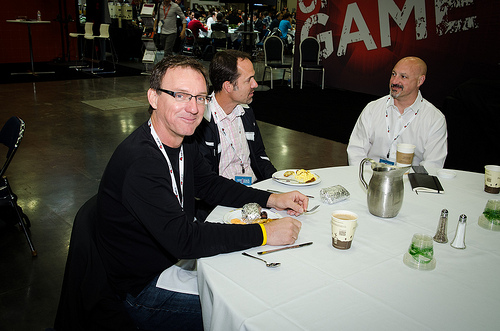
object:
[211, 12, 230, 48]
people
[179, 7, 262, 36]
outdoors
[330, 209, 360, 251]
cup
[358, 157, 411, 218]
coffee